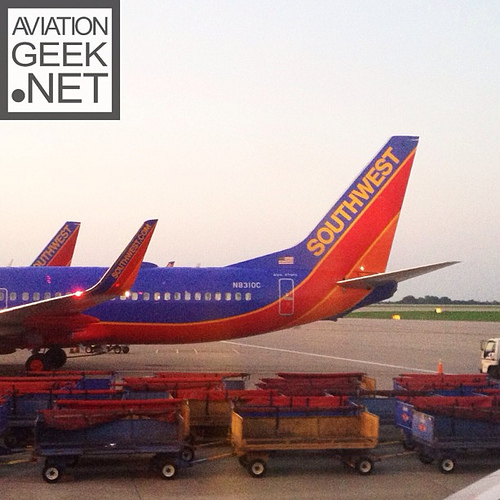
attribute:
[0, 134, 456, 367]
plane — southwest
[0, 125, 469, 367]
airplane — huge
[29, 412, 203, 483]
suv — black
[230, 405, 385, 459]
cart — wooden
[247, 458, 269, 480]
wheel — black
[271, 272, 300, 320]
door — closed, small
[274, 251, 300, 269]
flag — american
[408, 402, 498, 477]
cart — blue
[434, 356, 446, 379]
cone — orange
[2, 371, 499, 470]
wagons — blue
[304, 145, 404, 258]
word — yellow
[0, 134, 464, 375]
airliner — jet